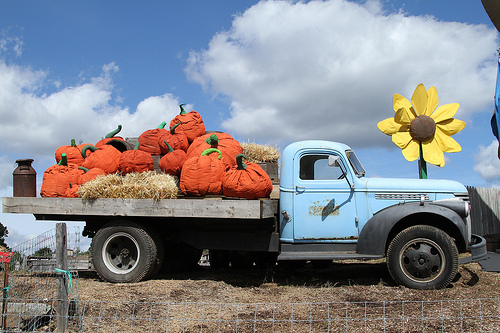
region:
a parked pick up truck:
[4, 138, 487, 287]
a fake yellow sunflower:
[378, 82, 465, 177]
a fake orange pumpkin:
[223, 154, 274, 199]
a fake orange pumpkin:
[181, 146, 221, 193]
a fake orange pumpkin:
[188, 130, 242, 167]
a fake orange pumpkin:
[168, 101, 203, 139]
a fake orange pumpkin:
[156, 120, 190, 152]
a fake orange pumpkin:
[155, 140, 187, 174]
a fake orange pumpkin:
[140, 120, 168, 151]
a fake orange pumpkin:
[119, 140, 157, 172]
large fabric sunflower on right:
[358, 78, 486, 187]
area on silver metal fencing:
[333, 296, 405, 331]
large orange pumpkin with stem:
[184, 145, 230, 190]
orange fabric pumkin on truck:
[181, 139, 226, 199]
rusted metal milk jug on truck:
[1, 130, 47, 207]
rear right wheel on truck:
[82, 211, 184, 301]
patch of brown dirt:
[174, 285, 236, 330]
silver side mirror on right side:
[326, 140, 360, 177]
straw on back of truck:
[94, 165, 168, 207]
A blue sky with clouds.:
[1, 1, 499, 258]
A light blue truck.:
[1, 139, 489, 291]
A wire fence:
[1, 223, 499, 332]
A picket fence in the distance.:
[465, 184, 499, 241]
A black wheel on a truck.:
[385, 224, 458, 292]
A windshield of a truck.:
[345, 148, 365, 176]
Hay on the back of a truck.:
[75, 170, 177, 199]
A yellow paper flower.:
[377, 84, 467, 179]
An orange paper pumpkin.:
[222, 154, 274, 199]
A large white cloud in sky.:
[175, 1, 499, 154]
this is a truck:
[49, 100, 480, 307]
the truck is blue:
[268, 113, 468, 293]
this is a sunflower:
[355, 55, 470, 190]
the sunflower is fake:
[337, 28, 472, 192]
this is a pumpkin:
[170, 133, 238, 195]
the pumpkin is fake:
[158, 134, 240, 213]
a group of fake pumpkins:
[28, 85, 281, 227]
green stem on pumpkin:
[196, 139, 228, 168]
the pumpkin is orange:
[180, 147, 243, 197]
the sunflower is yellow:
[375, 48, 477, 178]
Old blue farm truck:
[3, 98, 476, 293]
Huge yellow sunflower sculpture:
[378, 82, 468, 178]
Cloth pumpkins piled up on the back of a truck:
[33, 99, 273, 205]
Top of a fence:
[5, 225, 495, 326]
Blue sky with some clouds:
[3, 1, 499, 262]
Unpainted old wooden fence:
[453, 179, 498, 253]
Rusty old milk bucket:
[10, 152, 39, 196]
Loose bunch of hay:
[79, 167, 177, 204]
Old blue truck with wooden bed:
[0, 100, 488, 300]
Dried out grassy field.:
[0, 253, 497, 330]